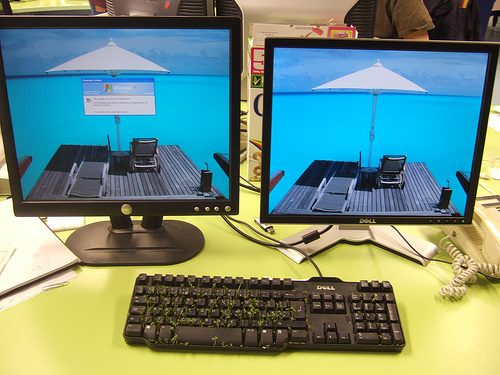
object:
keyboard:
[122, 272, 405, 353]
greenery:
[142, 280, 311, 346]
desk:
[0, 104, 498, 373]